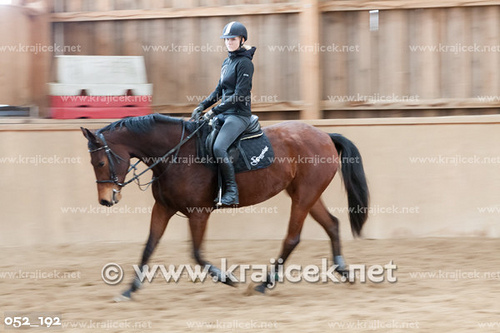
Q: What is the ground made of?
A: Dirt.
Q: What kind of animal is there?
A: A horse.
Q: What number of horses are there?
A: One.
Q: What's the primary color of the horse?
A: Brown.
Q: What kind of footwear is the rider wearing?
A: Boots.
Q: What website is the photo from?
A: Www.krajicek.net.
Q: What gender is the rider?
A: Female.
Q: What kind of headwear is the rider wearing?
A: A helmet.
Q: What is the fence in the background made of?
A: Wood.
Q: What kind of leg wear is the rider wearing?
A: Pants.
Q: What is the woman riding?
A: A horse.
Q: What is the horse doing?
A: Walking.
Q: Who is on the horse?
A: A lady.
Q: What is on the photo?
A: A website.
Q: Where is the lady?
A: On a horse.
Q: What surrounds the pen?
A: Wooden fence.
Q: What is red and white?
A: Supply box.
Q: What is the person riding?
A: A horse.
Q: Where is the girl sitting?
A: On top of horse.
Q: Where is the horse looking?
A: Down at ground.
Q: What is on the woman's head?
A: Riding helmet.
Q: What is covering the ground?
A: Dirt.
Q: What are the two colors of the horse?
A: Brown and black.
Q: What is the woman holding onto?
A: Reigns.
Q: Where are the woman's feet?
A: In stirrups.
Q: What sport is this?
A: Equestrian.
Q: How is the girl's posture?
A: Sitting upright.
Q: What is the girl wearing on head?
A: A helmet.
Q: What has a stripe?
A: The helmet.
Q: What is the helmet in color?
A: Black.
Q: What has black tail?
A: The horse.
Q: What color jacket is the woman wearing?
A: Black.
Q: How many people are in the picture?
A: One.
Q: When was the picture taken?
A: During the day.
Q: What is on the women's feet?
A: Riding boots.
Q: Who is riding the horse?
A: A women.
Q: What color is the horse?
A: Brown.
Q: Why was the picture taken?
A: To capture the women.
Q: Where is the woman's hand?
A: On the reins.